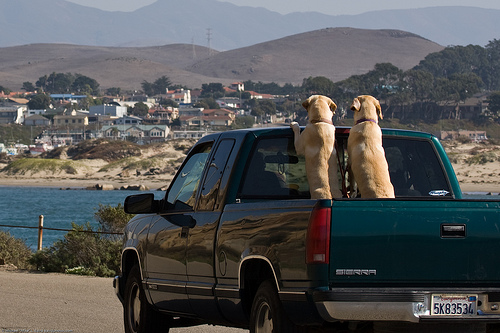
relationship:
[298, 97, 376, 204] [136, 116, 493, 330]
dogs in truck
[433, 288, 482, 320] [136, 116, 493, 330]
tag on truck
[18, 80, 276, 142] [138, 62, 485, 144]
houses on hill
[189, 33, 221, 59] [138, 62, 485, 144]
poles on hill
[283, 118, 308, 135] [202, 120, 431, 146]
paws on roof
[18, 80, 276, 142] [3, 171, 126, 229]
houses behind water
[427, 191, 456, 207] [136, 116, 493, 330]
sticker on truck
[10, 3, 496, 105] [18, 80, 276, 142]
mountains behind houses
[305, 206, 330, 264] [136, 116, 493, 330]
tail light on truck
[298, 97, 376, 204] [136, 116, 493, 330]
dogs inside truck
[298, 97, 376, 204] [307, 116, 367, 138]
dogs wear collars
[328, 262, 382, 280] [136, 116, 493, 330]
name on truck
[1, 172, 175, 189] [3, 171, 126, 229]
shoreline behind water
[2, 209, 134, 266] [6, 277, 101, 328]
fence near road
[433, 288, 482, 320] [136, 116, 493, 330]
tag on back of truck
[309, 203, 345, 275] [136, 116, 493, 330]
tail light on rear of truck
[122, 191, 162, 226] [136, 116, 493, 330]
mirror on side of truck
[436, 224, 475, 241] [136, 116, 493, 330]
latch on truck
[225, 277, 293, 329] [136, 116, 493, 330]
tire on back of truck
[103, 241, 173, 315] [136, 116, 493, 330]
tire on truck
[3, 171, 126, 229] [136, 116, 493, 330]
water near truck